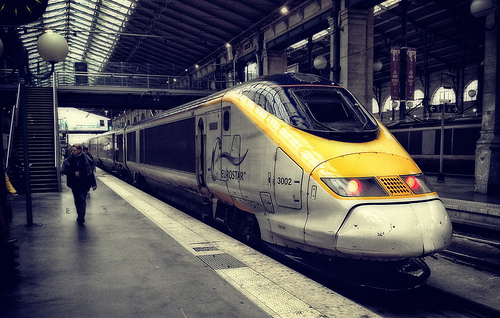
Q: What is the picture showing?
A: It is showing a station.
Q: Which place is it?
A: It is a station.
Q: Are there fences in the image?
A: No, there are no fences.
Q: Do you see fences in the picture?
A: No, there are no fences.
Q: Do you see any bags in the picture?
A: No, there are no bags.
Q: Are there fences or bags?
A: No, there are no bags or fences.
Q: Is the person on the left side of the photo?
A: Yes, the person is on the left of the image.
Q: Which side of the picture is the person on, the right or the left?
A: The person is on the left of the image.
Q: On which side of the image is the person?
A: The person is on the left of the image.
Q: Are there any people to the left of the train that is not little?
A: Yes, there is a person to the left of the train.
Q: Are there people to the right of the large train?
A: No, the person is to the left of the train.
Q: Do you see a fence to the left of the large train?
A: No, there is a person to the left of the train.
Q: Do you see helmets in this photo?
A: No, there are no helmets.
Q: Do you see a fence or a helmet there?
A: No, there are no helmets or fences.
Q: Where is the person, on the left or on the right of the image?
A: The person is on the left of the image.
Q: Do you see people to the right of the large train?
A: No, the person is to the left of the train.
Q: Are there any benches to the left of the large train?
A: No, there is a person to the left of the train.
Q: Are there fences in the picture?
A: No, there are no fences.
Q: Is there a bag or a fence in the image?
A: No, there are no fences or bags.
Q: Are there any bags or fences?
A: No, there are no fences or bags.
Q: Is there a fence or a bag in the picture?
A: No, there are no fences or bags.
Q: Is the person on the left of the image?
A: Yes, the person is on the left of the image.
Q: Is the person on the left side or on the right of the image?
A: The person is on the left of the image.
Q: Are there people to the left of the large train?
A: Yes, there is a person to the left of the train.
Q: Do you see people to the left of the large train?
A: Yes, there is a person to the left of the train.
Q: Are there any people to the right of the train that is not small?
A: No, the person is to the left of the train.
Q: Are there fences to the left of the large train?
A: No, there is a person to the left of the train.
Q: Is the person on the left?
A: Yes, the person is on the left of the image.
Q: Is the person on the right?
A: No, the person is on the left of the image.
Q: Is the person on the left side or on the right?
A: The person is on the left of the image.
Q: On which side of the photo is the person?
A: The person is on the left of the image.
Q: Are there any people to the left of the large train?
A: Yes, there is a person to the left of the train.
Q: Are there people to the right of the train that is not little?
A: No, the person is to the left of the train.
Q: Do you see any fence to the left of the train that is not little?
A: No, there is a person to the left of the train.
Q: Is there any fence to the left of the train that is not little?
A: No, there is a person to the left of the train.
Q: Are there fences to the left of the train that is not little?
A: No, there is a person to the left of the train.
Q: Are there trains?
A: Yes, there is a train.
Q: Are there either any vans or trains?
A: Yes, there is a train.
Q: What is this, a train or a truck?
A: This is a train.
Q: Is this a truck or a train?
A: This is a train.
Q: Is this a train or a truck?
A: This is a train.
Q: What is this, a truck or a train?
A: This is a train.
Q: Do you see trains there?
A: Yes, there is a train.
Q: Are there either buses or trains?
A: Yes, there is a train.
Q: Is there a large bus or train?
A: Yes, there is a large train.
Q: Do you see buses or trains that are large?
A: Yes, the train is large.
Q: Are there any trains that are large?
A: Yes, there is a large train.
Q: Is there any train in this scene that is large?
A: Yes, there is a train that is large.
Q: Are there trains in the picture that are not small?
A: Yes, there is a large train.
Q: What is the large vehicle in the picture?
A: The vehicle is a train.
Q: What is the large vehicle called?
A: The vehicle is a train.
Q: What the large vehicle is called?
A: The vehicle is a train.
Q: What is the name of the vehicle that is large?
A: The vehicle is a train.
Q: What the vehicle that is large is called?
A: The vehicle is a train.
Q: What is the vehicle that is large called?
A: The vehicle is a train.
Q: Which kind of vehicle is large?
A: The vehicle is a train.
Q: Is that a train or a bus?
A: That is a train.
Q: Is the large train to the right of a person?
A: Yes, the train is to the right of a person.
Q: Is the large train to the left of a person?
A: No, the train is to the right of a person.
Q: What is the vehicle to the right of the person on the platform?
A: The vehicle is a train.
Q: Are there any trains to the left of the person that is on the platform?
A: No, the train is to the right of the person.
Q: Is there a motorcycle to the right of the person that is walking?
A: No, there is a train to the right of the person.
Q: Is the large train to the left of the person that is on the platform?
A: No, the train is to the right of the person.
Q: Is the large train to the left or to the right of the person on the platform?
A: The train is to the right of the person.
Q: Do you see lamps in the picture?
A: Yes, there is a lamp.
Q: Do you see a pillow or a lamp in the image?
A: Yes, there is a lamp.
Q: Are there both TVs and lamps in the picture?
A: No, there is a lamp but no televisions.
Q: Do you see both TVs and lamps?
A: No, there is a lamp but no televisions.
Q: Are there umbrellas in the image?
A: No, there are no umbrellas.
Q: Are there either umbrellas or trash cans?
A: No, there are no umbrellas or trash cans.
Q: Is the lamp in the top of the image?
A: Yes, the lamp is in the top of the image.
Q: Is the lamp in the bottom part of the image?
A: No, the lamp is in the top of the image.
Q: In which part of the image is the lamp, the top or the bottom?
A: The lamp is in the top of the image.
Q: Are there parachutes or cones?
A: No, there are no cones or parachutes.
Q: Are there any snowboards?
A: No, there are no snowboards.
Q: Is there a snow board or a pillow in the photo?
A: No, there are no snowboards or pillows.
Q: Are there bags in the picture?
A: No, there are no bags.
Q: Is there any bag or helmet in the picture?
A: No, there are no bags or helmets.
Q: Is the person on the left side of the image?
A: Yes, the person is on the left of the image.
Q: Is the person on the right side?
A: No, the person is on the left of the image.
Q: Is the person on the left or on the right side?
A: The person is on the left of the image.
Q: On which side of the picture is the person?
A: The person is on the left of the image.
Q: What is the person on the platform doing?
A: The person is walking.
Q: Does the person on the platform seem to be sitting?
A: No, the person is walking.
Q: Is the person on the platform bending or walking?
A: The person is walking.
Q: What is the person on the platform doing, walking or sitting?
A: The person is walking.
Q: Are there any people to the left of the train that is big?
A: Yes, there is a person to the left of the train.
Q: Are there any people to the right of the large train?
A: No, the person is to the left of the train.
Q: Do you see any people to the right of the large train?
A: No, the person is to the left of the train.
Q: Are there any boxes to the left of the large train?
A: No, there is a person to the left of the train.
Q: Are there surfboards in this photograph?
A: No, there are no surfboards.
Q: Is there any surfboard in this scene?
A: No, there are no surfboards.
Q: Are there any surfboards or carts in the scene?
A: No, there are no surfboards or carts.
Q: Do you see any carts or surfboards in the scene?
A: No, there are no surfboards or carts.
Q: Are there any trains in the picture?
A: Yes, there is a train.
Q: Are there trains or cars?
A: Yes, there is a train.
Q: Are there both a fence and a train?
A: No, there is a train but no fences.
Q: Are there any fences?
A: No, there are no fences.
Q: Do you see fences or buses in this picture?
A: No, there are no fences or buses.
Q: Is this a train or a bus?
A: This is a train.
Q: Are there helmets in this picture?
A: No, there are no helmets.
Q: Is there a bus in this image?
A: No, there are no buses.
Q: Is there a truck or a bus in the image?
A: No, there are no buses or trucks.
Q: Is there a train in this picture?
A: Yes, there is a train.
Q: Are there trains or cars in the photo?
A: Yes, there is a train.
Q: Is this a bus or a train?
A: This is a train.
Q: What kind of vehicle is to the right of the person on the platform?
A: The vehicle is a train.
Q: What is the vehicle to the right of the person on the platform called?
A: The vehicle is a train.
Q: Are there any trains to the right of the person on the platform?
A: Yes, there is a train to the right of the person.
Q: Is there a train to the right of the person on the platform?
A: Yes, there is a train to the right of the person.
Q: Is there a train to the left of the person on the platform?
A: No, the train is to the right of the person.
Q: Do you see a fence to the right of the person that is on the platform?
A: No, there is a train to the right of the person.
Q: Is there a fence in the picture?
A: No, there are no fences.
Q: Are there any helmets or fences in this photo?
A: No, there are no fences or helmets.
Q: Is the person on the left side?
A: Yes, the person is on the left of the image.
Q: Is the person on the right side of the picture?
A: No, the person is on the left of the image.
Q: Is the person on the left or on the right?
A: The person is on the left of the image.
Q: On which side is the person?
A: The person is on the left of the image.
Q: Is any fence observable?
A: No, there are no fences.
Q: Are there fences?
A: No, there are no fences.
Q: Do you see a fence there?
A: No, there are no fences.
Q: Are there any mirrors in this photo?
A: No, there are no mirrors.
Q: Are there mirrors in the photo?
A: No, there are no mirrors.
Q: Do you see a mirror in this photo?
A: No, there are no mirrors.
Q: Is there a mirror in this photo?
A: No, there are no mirrors.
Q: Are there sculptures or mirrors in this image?
A: No, there are no mirrors or sculptures.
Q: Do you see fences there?
A: No, there are no fences.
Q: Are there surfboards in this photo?
A: No, there are no surfboards.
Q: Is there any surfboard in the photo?
A: No, there are no surfboards.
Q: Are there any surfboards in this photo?
A: No, there are no surfboards.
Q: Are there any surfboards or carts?
A: No, there are no surfboards or carts.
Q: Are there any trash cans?
A: No, there are no trash cans.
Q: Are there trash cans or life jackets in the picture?
A: No, there are no trash cans or life jackets.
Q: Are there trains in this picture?
A: Yes, there is a train.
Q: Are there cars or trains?
A: Yes, there is a train.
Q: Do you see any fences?
A: No, there are no fences.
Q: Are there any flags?
A: Yes, there is a flag.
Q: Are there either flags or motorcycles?
A: Yes, there is a flag.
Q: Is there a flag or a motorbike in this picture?
A: Yes, there is a flag.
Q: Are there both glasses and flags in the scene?
A: No, there is a flag but no glasses.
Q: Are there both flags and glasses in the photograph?
A: No, there is a flag but no glasses.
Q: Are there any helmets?
A: No, there are no helmets.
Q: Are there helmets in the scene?
A: No, there are no helmets.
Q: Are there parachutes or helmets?
A: No, there are no helmets or parachutes.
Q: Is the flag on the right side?
A: Yes, the flag is on the right of the image.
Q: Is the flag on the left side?
A: No, the flag is on the right of the image.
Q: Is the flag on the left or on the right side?
A: The flag is on the right of the image.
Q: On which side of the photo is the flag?
A: The flag is on the right of the image.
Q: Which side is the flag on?
A: The flag is on the right of the image.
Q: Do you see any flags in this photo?
A: Yes, there is a flag.